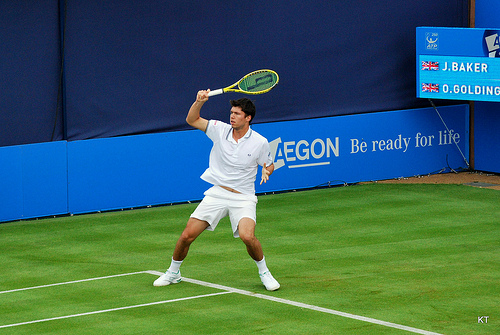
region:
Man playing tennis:
[124, 44, 314, 300]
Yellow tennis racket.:
[181, 61, 290, 102]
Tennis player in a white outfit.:
[131, 61, 306, 297]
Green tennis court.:
[1, 198, 494, 333]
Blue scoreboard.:
[409, 21, 499, 101]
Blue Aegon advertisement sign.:
[263, 98, 475, 200]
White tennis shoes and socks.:
[145, 251, 295, 296]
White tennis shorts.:
[168, 183, 270, 237]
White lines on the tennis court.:
[125, 265, 442, 332]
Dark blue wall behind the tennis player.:
[0, 0, 472, 148]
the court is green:
[294, 215, 429, 286]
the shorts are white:
[188, 191, 260, 229]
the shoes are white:
[153, 272, 308, 306]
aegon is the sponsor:
[290, 136, 423, 166]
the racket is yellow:
[193, 69, 307, 106]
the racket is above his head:
[196, 76, 306, 98]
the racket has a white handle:
[198, 71, 296, 111]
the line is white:
[210, 287, 338, 326]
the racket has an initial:
[188, 71, 311, 113]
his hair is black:
[230, 100, 265, 117]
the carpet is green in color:
[336, 197, 441, 310]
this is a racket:
[196, 65, 276, 91]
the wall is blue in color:
[96, 15, 151, 105]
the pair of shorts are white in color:
[192, 190, 247, 225]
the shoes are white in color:
[156, 265, 271, 282]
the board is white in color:
[91, 155, 161, 195]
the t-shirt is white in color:
[216, 135, 246, 177]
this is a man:
[155, 63, 277, 303]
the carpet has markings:
[47, 264, 142, 313]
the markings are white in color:
[188, 274, 252, 305]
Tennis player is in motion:
[147, 74, 292, 301]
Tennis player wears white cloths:
[144, 76, 298, 301]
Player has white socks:
[143, 72, 311, 304]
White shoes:
[140, 266, 293, 297]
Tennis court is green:
[5, 175, 497, 334]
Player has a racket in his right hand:
[188, 55, 284, 105]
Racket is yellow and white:
[197, 58, 283, 103]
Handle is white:
[196, 82, 226, 99]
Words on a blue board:
[273, 116, 476, 172]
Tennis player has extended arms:
[146, 54, 310, 306]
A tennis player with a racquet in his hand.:
[181, 63, 313, 283]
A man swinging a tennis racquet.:
[185, 76, 295, 108]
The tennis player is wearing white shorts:
[189, 180, 295, 233]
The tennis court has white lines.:
[75, 256, 317, 333]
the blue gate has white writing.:
[299, 131, 454, 171]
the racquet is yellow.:
[225, 73, 307, 102]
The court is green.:
[53, 223, 461, 317]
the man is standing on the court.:
[148, 120, 272, 292]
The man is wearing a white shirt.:
[203, 121, 286, 195]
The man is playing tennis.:
[177, 71, 345, 309]